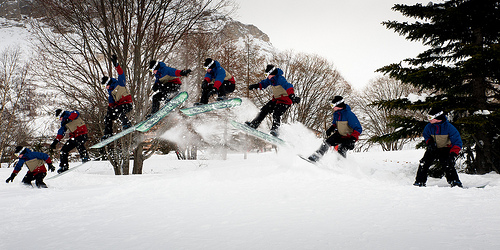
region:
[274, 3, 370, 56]
white clouds in blue sky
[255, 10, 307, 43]
white clouds in blue sky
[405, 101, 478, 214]
man doing trick on board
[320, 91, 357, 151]
man doing trick on board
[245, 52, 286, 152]
man doing trick on board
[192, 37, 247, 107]
man doing trick on board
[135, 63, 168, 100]
man doing trick on board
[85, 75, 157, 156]
man doing trick on board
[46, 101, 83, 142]
man doing trick on board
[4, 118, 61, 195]
man doing trick on board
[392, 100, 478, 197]
man standing in snow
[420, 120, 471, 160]
man's jacket is brown and blue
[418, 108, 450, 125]
man is wearing goggles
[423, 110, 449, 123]
the goggles are white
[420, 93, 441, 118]
man wearing a hat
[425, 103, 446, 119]
the hat is black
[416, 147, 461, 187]
man's pants are black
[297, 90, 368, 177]
man sliding up a hill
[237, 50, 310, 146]
the man is snowboarding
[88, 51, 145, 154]
man is in the air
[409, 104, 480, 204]
guy snowboarding in the snow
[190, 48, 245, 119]
guy in the air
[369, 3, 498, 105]
pine tree beside the guy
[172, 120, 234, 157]
spitting swirling white snow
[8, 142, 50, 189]
guy wearing goggles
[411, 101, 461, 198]
guy wearing black skipants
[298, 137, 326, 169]
snow covered leg of the guy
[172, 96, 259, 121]
snowboard in the air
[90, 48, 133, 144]
guy with his arm raised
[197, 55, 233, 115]
guy bent over on his snowboard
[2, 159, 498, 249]
Snow is covering the ground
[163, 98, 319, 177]
Snow is in the air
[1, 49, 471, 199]
A frame by frame shot of a snowboarder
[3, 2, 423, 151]
Bare trees in the background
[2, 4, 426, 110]
The sky is gray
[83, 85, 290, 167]
The snowboard is light green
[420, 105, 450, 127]
Snowboarder is wearing goggles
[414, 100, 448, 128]
Snowboarder's goggles are white in color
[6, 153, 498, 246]
Snow on the ground is white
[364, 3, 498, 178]
A pine tree in the foreground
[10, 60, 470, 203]
A photographic special effect featuring the multiplied image of a skier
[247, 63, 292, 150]
A skier on a snowboard in mid-jump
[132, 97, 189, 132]
A green and white snowboard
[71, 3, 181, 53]
A sparse leafless tree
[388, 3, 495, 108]
A bushy pine tree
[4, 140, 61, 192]
A person in winter clothes up to their knees in snow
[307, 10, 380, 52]
A gray empty sky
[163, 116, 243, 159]
Scattering blown snow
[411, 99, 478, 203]
A snowboarder semi-crouched in the snow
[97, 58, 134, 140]
A snowboarder completing a jump with arm raised